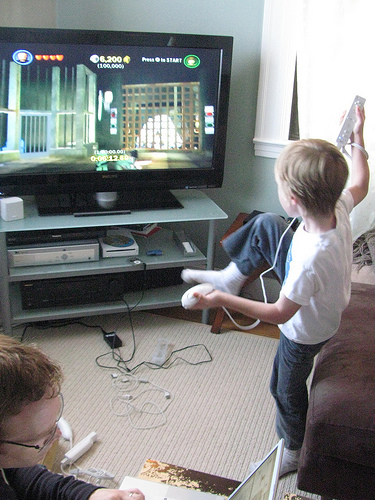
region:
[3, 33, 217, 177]
Lego video game on TV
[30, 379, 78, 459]
Boy wearing glasses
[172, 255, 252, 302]
Boy's right sock is white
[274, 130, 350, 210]
Boy's hair is blonde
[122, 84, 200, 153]
Bars of dungeon in game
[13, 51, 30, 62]
Small lego character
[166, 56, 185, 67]
Says Start on screen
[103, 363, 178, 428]
Headphones on ground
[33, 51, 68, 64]
Four red hearts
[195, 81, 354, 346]
Little boy playing Nintendo Wii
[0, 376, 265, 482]
Little boy wearing glasses looks at laptop screen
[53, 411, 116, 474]
An additional Nintendo Wii controller on the floor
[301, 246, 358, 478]
The corner of a brown cushioned sofa or chair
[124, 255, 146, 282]
iPod nano plugged into a device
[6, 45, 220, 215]
Flat screen TV display video game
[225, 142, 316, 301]
Boy lifts leg up to play interactive video game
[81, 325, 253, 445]
Cords laying on beige rug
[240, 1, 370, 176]
Grey walls and white window frame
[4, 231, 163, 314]
Audio visual equipment and video games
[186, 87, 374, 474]
a kid playing a video game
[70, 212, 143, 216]
a black sensor bar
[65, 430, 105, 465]
a white game controller on the floor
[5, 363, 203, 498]
a man looking at a laptop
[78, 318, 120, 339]
a black cord on the floor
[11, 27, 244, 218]
a large flat screen tv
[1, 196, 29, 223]
a small square speaker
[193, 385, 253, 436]
a beige rug on the floor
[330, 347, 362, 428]
the corner of dark brown sofa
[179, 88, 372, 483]
Boy playing a video game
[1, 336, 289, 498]
Man looking at a computer screen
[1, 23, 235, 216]
Large, black, flatscreen TV set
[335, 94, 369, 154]
White game controller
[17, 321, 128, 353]
Black power supply with black cord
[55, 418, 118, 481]
Video game controller sitting unused on the floor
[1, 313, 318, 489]
White area rug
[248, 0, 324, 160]
White window casement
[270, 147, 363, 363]
Blond child in white t-shirt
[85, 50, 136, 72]
Game score shown on TV screen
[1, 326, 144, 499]
man wearing glasses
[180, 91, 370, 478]
young boy in a white tee shirt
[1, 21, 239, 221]
large black flat screen television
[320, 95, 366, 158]
wii game console remote control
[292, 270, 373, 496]
brown couch cushion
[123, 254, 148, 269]
small silver ipod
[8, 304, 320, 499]
striped taupe carpet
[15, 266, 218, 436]
jumble of miscellaneous electrical cords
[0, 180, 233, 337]
silver metal and glass entertainment center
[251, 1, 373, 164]
painted white wood framed window